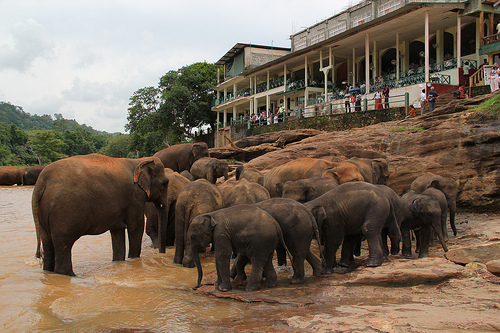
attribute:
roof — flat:
[211, 41, 290, 69]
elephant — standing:
[186, 194, 286, 301]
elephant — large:
[9, 124, 207, 306]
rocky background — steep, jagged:
[250, 108, 492, 184]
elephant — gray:
[185, 202, 287, 299]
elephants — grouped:
[28, 137, 465, 296]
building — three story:
[203, 14, 498, 149]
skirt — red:
[368, 95, 386, 115]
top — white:
[364, 80, 389, 101]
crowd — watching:
[246, 72, 393, 110]